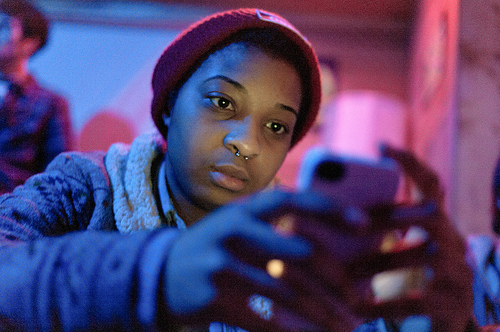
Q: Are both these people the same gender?
A: No, they are both male and female.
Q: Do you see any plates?
A: No, there are no plates.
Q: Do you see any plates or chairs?
A: No, there are no plates or chairs.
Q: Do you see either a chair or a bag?
A: No, there are no chairs or bags.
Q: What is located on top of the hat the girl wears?
A: The label is on top of the hat.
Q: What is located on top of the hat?
A: The label is on top of the hat.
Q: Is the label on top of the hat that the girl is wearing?
A: Yes, the label is on top of the hat.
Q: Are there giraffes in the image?
A: No, there are no giraffes.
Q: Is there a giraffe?
A: No, there are no giraffes.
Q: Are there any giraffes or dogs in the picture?
A: No, there are no giraffes or dogs.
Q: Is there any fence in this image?
A: No, there are no fences.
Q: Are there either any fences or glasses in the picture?
A: No, there are no fences or glasses.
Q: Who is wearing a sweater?
A: The girl is wearing a sweater.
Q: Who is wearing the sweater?
A: The girl is wearing a sweater.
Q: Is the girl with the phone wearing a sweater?
A: Yes, the girl is wearing a sweater.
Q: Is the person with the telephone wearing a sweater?
A: Yes, the girl is wearing a sweater.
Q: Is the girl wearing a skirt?
A: No, the girl is wearing a sweater.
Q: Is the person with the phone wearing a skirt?
A: No, the girl is wearing a sweater.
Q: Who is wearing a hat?
A: The girl is wearing a hat.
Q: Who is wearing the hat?
A: The girl is wearing a hat.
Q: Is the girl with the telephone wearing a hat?
A: Yes, the girl is wearing a hat.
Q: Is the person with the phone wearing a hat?
A: Yes, the girl is wearing a hat.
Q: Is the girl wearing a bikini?
A: No, the girl is wearing a hat.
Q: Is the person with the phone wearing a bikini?
A: No, the girl is wearing a hat.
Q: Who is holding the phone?
A: The girl is holding the phone.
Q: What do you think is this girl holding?
A: The girl is holding the phone.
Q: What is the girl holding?
A: The girl is holding the phone.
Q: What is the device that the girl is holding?
A: The device is a phone.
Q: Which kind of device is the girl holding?
A: The girl is holding the phone.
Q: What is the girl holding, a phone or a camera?
A: The girl is holding a phone.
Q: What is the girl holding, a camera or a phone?
A: The girl is holding a phone.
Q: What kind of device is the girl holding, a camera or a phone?
A: The girl is holding a phone.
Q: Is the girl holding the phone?
A: Yes, the girl is holding the phone.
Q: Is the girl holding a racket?
A: No, the girl is holding the phone.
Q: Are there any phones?
A: Yes, there is a phone.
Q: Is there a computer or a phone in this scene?
A: Yes, there is a phone.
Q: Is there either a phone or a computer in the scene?
A: Yes, there is a phone.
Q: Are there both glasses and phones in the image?
A: No, there is a phone but no glasses.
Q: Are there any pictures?
A: No, there are no pictures.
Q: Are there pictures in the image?
A: No, there are no pictures.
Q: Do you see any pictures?
A: No, there are no pictures.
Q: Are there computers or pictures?
A: No, there are no pictures or computers.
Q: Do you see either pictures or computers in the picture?
A: No, there are no pictures or computers.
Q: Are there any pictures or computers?
A: No, there are no pictures or computers.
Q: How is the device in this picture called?
A: The device is a phone.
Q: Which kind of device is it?
A: The device is a phone.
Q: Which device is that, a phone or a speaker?
A: This is a phone.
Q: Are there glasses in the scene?
A: No, there are no glasses.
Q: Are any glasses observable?
A: No, there are no glasses.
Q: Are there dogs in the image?
A: No, there are no dogs.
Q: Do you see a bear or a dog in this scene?
A: No, there are no dogs or bears.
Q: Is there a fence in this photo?
A: No, there are no fences.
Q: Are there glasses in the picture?
A: No, there are no glasses.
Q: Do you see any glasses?
A: No, there are no glasses.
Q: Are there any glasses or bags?
A: No, there are no glasses or bags.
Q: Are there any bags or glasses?
A: No, there are no glasses or bags.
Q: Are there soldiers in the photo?
A: No, there are no soldiers.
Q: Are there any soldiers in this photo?
A: No, there are no soldiers.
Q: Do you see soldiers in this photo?
A: No, there are no soldiers.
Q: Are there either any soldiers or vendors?
A: No, there are no soldiers or vendors.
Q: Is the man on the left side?
A: Yes, the man is on the left of the image.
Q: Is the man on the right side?
A: No, the man is on the left of the image.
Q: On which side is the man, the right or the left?
A: The man is on the left of the image.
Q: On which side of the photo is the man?
A: The man is on the left of the image.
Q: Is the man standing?
A: Yes, the man is standing.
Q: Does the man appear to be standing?
A: Yes, the man is standing.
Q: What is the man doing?
A: The man is standing.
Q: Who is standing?
A: The man is standing.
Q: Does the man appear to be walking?
A: No, the man is standing.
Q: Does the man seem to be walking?
A: No, the man is standing.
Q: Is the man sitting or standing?
A: The man is standing.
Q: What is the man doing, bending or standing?
A: The man is standing.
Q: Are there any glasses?
A: No, there are no glasses.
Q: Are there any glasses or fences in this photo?
A: No, there are no glasses or fences.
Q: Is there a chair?
A: No, there are no chairs.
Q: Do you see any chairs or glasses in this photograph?
A: No, there are no chairs or glasses.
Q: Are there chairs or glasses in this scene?
A: No, there are no chairs or glasses.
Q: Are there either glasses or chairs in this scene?
A: No, there are no chairs or glasses.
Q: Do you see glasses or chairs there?
A: No, there are no chairs or glasses.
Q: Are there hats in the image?
A: Yes, there is a hat.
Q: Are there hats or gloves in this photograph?
A: Yes, there is a hat.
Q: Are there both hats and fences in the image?
A: No, there is a hat but no fences.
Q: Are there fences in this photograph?
A: No, there are no fences.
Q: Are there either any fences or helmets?
A: No, there are no fences or helmets.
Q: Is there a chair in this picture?
A: No, there are no chairs.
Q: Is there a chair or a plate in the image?
A: No, there are no chairs or plates.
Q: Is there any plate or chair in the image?
A: No, there are no chairs or plates.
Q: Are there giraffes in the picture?
A: No, there are no giraffes.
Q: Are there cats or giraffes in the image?
A: No, there are no giraffes or cats.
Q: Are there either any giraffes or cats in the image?
A: No, there are no giraffes or cats.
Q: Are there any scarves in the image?
A: Yes, there is a scarf.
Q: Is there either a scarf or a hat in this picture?
A: Yes, there is a scarf.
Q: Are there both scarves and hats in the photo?
A: Yes, there are both a scarf and a hat.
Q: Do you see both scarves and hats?
A: Yes, there are both a scarf and a hat.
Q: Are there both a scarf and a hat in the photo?
A: Yes, there are both a scarf and a hat.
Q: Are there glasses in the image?
A: No, there are no glasses.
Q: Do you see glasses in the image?
A: No, there are no glasses.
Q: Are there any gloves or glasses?
A: No, there are no glasses or gloves.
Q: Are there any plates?
A: No, there are no plates.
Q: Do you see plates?
A: No, there are no plates.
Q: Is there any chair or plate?
A: No, there are no plates or chairs.